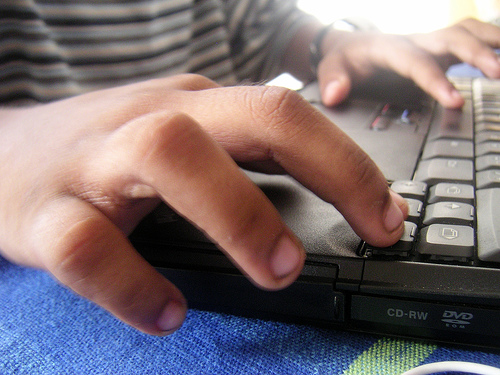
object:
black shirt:
[0, 0, 319, 111]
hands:
[0, 72, 411, 338]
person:
[0, 0, 499, 337]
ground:
[369, 76, 500, 273]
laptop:
[118, 70, 500, 352]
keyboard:
[361, 71, 499, 273]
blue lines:
[0, 28, 199, 38]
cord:
[393, 358, 500, 374]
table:
[0, 260, 497, 375]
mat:
[344, 335, 499, 375]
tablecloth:
[0, 258, 500, 373]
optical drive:
[347, 295, 500, 337]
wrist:
[318, 21, 364, 63]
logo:
[441, 311, 474, 330]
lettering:
[386, 307, 428, 321]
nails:
[267, 235, 302, 279]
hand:
[317, 17, 500, 109]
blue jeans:
[0, 253, 382, 375]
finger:
[14, 191, 187, 337]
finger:
[92, 109, 308, 293]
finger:
[181, 85, 405, 249]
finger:
[366, 35, 464, 112]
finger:
[429, 24, 500, 82]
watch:
[313, 18, 363, 60]